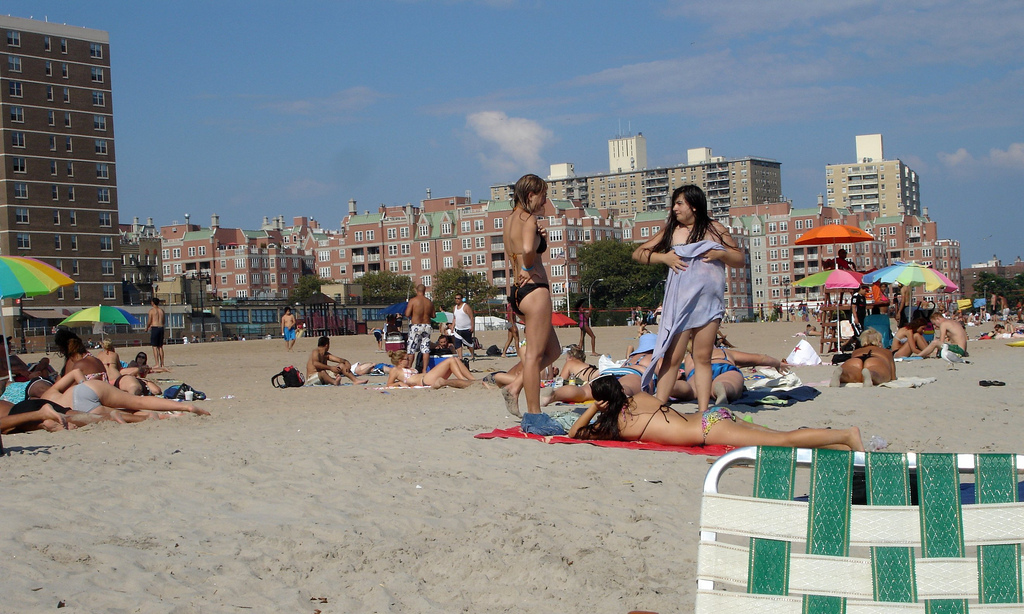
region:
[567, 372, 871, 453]
Woman in bikini sunbathing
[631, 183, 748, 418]
Woman wrapping towel around her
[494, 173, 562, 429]
Woman standing in sand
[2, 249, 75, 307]
Rainbow colored umbrella in sand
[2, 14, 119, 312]
Large brick building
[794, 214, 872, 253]
Orange umbrella sticking out of sand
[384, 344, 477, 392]
Woman laying down in sand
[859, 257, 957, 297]
Multi colored umbrella in sand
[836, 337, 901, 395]
Person laying down in sand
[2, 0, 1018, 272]
White clouds in a blue sky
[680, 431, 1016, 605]
A green and white chair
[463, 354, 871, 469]
Woman lying down on a towel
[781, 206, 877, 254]
An open orange umbrella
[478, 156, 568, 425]
A woman has on a black bikini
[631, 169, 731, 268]
A girl has long dark hair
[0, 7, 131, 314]
Many windows on a brown building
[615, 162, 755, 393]
Girl has a blue blanket wrapped around her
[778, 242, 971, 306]
Two open colorful umbrellas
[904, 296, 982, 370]
A person is sitting down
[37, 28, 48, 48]
a window on a building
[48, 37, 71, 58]
a window on a building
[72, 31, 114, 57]
a window on a building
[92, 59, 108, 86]
a window on a building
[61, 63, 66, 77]
a window on a building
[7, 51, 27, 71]
a window on a building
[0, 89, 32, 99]
a window on a building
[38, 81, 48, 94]
a window on a building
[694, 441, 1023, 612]
Green and white striped lawn chair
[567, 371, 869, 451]
Woman in bikini laying on towel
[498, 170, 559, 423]
Woman standing in the sand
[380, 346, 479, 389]
Woman laying in the sand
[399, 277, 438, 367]
Man in swim trunks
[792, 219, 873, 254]
Orange umbrella in sand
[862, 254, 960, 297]
Multi colored umbrella shading people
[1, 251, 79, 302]
Rainbow umbrella shading people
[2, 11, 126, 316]
Large brick building with windows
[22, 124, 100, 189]
windows in the building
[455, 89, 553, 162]
clouds in the sky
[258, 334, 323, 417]
a bag on the sand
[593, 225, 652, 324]
a tree next to the building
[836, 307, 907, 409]
girl laying on the beach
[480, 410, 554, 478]
a towel on the ground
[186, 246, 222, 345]
a light by the building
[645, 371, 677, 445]
a black string on the girl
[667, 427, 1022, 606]
green and white striped chair back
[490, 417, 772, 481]
red beach towel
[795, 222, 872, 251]
open orange umbrella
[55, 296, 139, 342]
open rainbow striped umbrella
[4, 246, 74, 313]
open rainbow striped umbrella